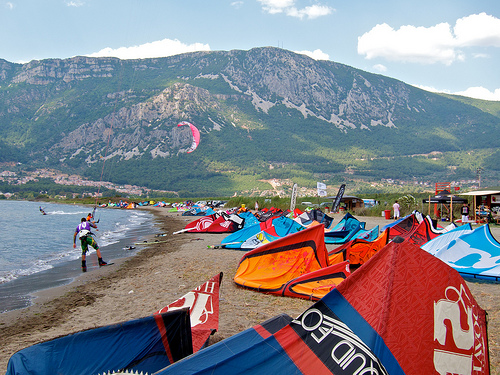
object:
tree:
[172, 185, 179, 192]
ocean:
[0, 195, 160, 317]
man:
[73, 217, 114, 272]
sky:
[0, 0, 500, 100]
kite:
[177, 121, 201, 154]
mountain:
[0, 45, 500, 202]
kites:
[0, 237, 493, 375]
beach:
[59, 186, 484, 352]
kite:
[174, 211, 245, 234]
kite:
[209, 212, 380, 250]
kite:
[420, 222, 500, 283]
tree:
[133, 173, 144, 185]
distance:
[0, 37, 499, 200]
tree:
[89, 164, 96, 171]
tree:
[150, 191, 157, 198]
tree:
[142, 150, 151, 161]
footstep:
[81, 260, 87, 272]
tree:
[214, 168, 226, 176]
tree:
[270, 110, 285, 123]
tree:
[321, 124, 331, 138]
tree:
[255, 128, 271, 151]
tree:
[255, 124, 276, 149]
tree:
[160, 156, 168, 167]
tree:
[204, 129, 216, 154]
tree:
[110, 166, 124, 176]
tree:
[415, 140, 426, 153]